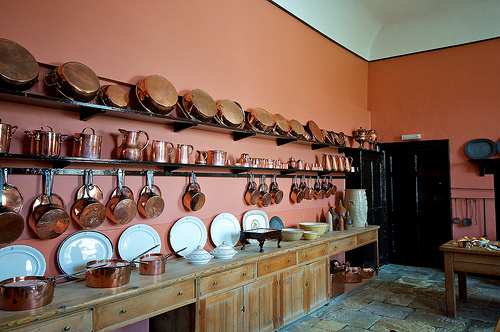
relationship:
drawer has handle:
[197, 264, 259, 290] [243, 267, 250, 277]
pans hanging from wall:
[26, 167, 212, 217] [2, 1, 406, 262]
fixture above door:
[400, 130, 423, 139] [387, 140, 445, 266]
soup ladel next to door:
[452, 195, 482, 227] [387, 140, 445, 266]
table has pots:
[23, 221, 387, 331] [94, 254, 137, 287]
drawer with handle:
[197, 264, 259, 290] [243, 267, 250, 277]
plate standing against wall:
[118, 221, 162, 259] [2, 1, 406, 262]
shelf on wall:
[3, 130, 368, 188] [2, 1, 406, 262]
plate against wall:
[118, 221, 162, 259] [2, 1, 406, 262]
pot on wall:
[133, 174, 159, 211] [2, 1, 406, 262]